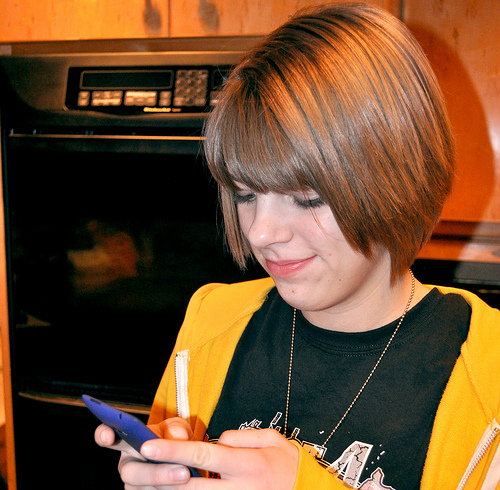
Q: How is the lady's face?
A: Smiling.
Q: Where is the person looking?
A: Phone.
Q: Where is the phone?
A: Hand.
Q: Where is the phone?
A: In the woman's hands.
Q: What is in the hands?
A: A phone.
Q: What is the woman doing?
A: Texting.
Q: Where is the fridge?
A: Behind the woman.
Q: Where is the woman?
A: In the kitchen.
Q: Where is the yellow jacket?
A: On the woman.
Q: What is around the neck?
A: A necklace.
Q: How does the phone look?
A: Purple.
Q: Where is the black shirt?
A: On the woman.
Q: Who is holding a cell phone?
A: A woman.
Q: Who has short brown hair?
A: A lady.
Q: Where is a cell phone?
A: In woman's hands.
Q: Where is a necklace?
A: Around girl's neck.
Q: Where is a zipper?
A: On yellow sweater.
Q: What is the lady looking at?
A: Cell phone.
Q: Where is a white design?
A: On black shirt.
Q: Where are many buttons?
A: On black oven.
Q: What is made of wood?
A: Cabinets.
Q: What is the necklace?
A: Chain.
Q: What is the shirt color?
A: Black.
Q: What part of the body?
A: Hand.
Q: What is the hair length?
A: Short.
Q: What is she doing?
A: Texting.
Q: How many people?
A: 1.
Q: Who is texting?
A: The lady.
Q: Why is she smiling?
A: Happy.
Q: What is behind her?
A: Cabinets.